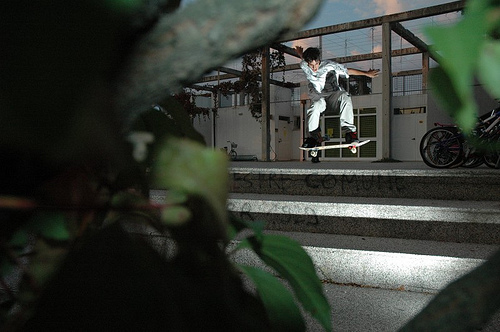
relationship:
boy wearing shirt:
[292, 41, 379, 145] [298, 58, 349, 93]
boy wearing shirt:
[292, 41, 379, 145] [301, 62, 352, 99]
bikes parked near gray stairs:
[418, 113, 497, 177] [218, 167, 499, 294]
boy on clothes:
[292, 41, 379, 145] [295, 58, 350, 133]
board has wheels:
[298, 137, 372, 157] [308, 150, 320, 156]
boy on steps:
[292, 41, 379, 145] [223, 160, 499, 242]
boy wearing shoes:
[292, 41, 379, 145] [299, 114, 379, 171]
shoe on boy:
[346, 133, 356, 146] [292, 41, 379, 145]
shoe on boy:
[302, 136, 322, 148] [292, 41, 379, 145]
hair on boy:
[292, 45, 335, 62] [292, 41, 379, 145]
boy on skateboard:
[292, 41, 382, 145] [297, 137, 372, 157]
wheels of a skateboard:
[311, 148, 360, 156] [297, 137, 372, 157]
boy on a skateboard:
[292, 41, 382, 145] [295, 137, 372, 159]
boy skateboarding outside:
[292, 41, 379, 145] [0, 0, 499, 330]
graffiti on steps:
[231, 165, 458, 200] [235, 161, 487, 237]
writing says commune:
[281, 151, 405, 192] [279, 166, 425, 204]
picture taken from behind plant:
[2, 0, 496, 327] [1, 6, 325, 330]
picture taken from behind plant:
[2, 0, 496, 327] [430, 1, 497, 133]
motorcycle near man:
[416, 95, 498, 170] [305, 51, 382, 141]